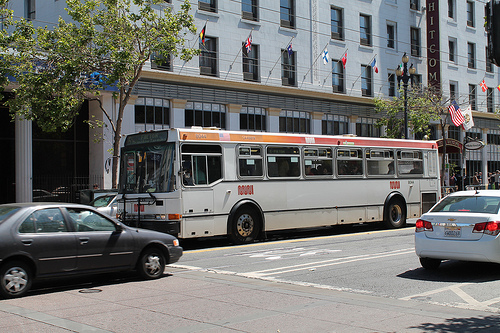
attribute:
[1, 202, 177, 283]
car — grey, gray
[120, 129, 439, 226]
bus — red, white, orange, long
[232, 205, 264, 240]
wheel — black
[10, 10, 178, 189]
tree — green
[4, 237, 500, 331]
road — asphalt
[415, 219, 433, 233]
brake light — red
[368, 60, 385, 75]
flag — red white, blue